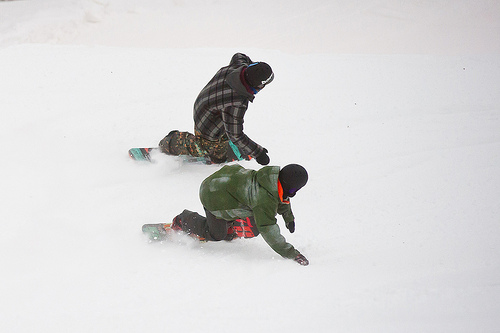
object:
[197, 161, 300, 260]
clothing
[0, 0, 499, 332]
snow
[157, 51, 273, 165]
child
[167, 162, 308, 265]
child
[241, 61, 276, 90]
head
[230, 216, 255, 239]
design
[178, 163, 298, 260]
snowsuit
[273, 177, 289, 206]
collar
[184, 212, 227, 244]
leg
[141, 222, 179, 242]
ski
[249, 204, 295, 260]
right arm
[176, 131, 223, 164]
leg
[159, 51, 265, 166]
snowsuit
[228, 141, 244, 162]
design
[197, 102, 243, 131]
stripe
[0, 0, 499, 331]
ground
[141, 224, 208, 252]
snow spray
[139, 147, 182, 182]
snow spray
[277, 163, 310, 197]
cap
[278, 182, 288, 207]
lining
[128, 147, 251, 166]
snowboard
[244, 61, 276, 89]
helmet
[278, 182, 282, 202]
orange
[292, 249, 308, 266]
hand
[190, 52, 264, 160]
coat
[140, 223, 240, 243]
snowboard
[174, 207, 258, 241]
pants